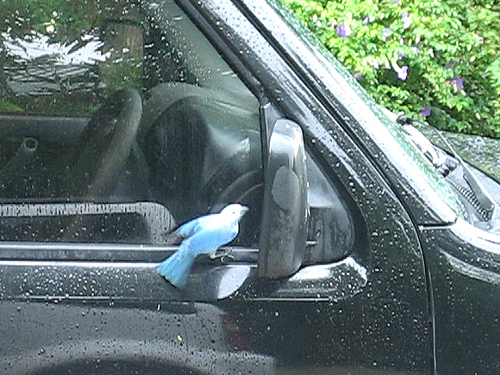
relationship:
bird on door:
[174, 199, 245, 273] [37, 276, 185, 338]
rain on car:
[195, 67, 196, 68] [1, 32, 462, 331]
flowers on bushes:
[330, 21, 385, 48] [420, 3, 460, 28]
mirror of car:
[256, 114, 341, 284] [1, 32, 462, 331]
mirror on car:
[256, 114, 341, 284] [1, 32, 462, 331]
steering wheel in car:
[46, 87, 149, 206] [1, 32, 462, 331]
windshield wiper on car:
[443, 134, 489, 206] [1, 32, 462, 331]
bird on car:
[174, 199, 245, 273] [1, 32, 462, 331]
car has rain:
[1, 32, 462, 331] [195, 67, 196, 68]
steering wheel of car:
[46, 87, 149, 206] [1, 32, 462, 331]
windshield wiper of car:
[443, 134, 489, 206] [1, 32, 462, 331]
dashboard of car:
[184, 80, 253, 120] [1, 32, 462, 331]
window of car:
[62, 0, 218, 62] [1, 32, 462, 331]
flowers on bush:
[330, 21, 385, 48] [311, 3, 360, 16]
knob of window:
[94, 242, 119, 261] [62, 0, 218, 62]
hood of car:
[471, 134, 497, 163] [1, 32, 462, 331]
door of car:
[37, 276, 185, 338] [1, 32, 462, 331]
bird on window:
[174, 199, 245, 273] [62, 0, 218, 62]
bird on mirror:
[174, 199, 245, 273] [256, 114, 341, 284]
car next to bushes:
[1, 32, 462, 331] [420, 3, 460, 28]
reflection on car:
[37, 32, 184, 60] [1, 32, 462, 331]